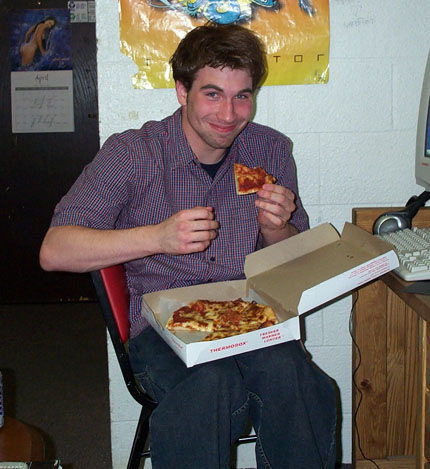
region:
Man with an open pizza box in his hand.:
[38, 16, 400, 466]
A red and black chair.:
[87, 261, 338, 463]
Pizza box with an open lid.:
[139, 220, 401, 367]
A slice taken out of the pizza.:
[165, 298, 279, 342]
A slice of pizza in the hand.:
[232, 161, 294, 226]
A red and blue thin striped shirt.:
[47, 106, 310, 341]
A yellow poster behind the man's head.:
[116, 0, 330, 90]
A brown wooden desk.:
[349, 207, 429, 468]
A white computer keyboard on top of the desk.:
[368, 226, 429, 281]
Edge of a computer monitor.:
[413, 47, 429, 189]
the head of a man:
[173, 55, 284, 154]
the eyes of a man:
[195, 86, 265, 112]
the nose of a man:
[209, 101, 250, 131]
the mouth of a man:
[201, 108, 261, 160]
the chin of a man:
[192, 126, 244, 175]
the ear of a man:
[166, 81, 199, 111]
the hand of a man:
[150, 201, 230, 257]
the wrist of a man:
[137, 223, 183, 266]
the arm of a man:
[35, 201, 228, 274]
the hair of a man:
[145, 33, 285, 114]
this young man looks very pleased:
[168, 17, 270, 151]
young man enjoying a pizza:
[37, 19, 404, 369]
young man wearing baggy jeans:
[119, 311, 347, 467]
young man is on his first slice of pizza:
[135, 159, 302, 359]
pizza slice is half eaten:
[226, 155, 283, 200]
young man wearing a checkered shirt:
[41, 102, 315, 337]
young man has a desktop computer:
[368, 37, 428, 286]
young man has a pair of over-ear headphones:
[368, 182, 428, 238]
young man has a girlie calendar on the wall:
[5, 4, 79, 136]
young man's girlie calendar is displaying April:
[5, 4, 78, 136]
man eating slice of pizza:
[37, 26, 343, 467]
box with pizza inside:
[139, 218, 403, 367]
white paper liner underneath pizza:
[158, 287, 285, 344]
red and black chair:
[89, 242, 297, 467]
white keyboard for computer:
[373, 221, 427, 279]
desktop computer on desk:
[411, 47, 424, 186]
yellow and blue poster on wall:
[118, 0, 329, 88]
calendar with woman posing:
[1, 1, 77, 133]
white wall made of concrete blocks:
[91, 0, 425, 463]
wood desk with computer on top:
[348, 205, 429, 467]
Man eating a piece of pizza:
[35, 21, 342, 466]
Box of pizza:
[134, 221, 403, 368]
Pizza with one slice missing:
[164, 294, 277, 341]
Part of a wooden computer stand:
[347, 206, 426, 467]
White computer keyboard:
[374, 226, 428, 280]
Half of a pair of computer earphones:
[371, 188, 428, 232]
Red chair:
[91, 264, 261, 467]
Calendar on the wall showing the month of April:
[6, 5, 72, 132]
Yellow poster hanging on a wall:
[121, 2, 332, 92]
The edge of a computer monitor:
[413, 46, 428, 194]